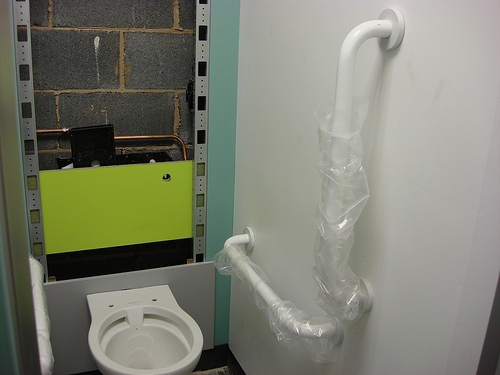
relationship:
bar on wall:
[322, 9, 402, 315] [227, 0, 498, 374]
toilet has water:
[85, 283, 205, 374] [129, 344, 157, 367]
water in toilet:
[129, 344, 157, 367] [85, 283, 205, 374]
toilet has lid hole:
[85, 283, 205, 374] [106, 300, 116, 309]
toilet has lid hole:
[85, 283, 205, 374] [149, 294, 159, 303]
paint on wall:
[91, 35, 104, 80] [32, 1, 196, 160]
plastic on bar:
[317, 118, 363, 320] [322, 9, 402, 315]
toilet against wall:
[85, 283, 205, 374] [32, 1, 196, 160]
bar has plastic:
[322, 9, 402, 315] [317, 118, 363, 320]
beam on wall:
[10, 1, 48, 278] [32, 1, 196, 160]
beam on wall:
[196, 1, 211, 262] [32, 1, 196, 160]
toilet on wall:
[85, 283, 205, 374] [32, 1, 196, 160]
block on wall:
[14, 28, 121, 91] [32, 1, 196, 160]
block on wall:
[51, 0, 175, 29] [32, 1, 196, 160]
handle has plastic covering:
[224, 226, 341, 352] [216, 248, 335, 368]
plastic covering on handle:
[216, 248, 335, 368] [224, 226, 341, 352]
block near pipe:
[59, 91, 178, 144] [36, 127, 69, 132]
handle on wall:
[224, 226, 341, 352] [227, 0, 498, 374]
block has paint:
[14, 28, 121, 91] [91, 35, 104, 80]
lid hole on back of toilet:
[106, 300, 116, 309] [85, 283, 205, 374]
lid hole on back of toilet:
[149, 294, 159, 303] [85, 283, 205, 374]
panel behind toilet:
[32, 260, 217, 374] [85, 283, 205, 374]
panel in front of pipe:
[68, 123, 118, 166] [36, 127, 69, 132]